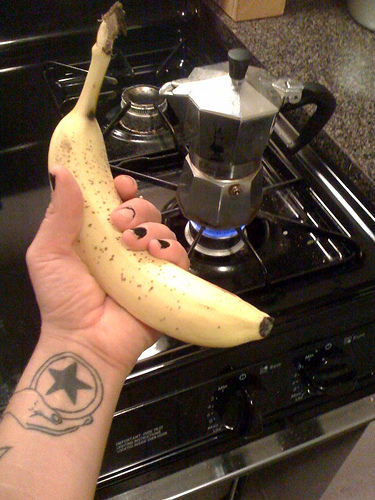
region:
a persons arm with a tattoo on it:
[3, 350, 105, 434]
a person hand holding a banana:
[29, 0, 273, 367]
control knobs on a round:
[206, 346, 361, 443]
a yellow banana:
[47, 1, 276, 346]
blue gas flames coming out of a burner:
[157, 183, 311, 267]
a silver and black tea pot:
[157, 36, 336, 229]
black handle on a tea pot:
[280, 74, 343, 158]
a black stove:
[0, 19, 373, 397]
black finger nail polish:
[129, 224, 157, 243]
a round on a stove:
[44, 37, 232, 155]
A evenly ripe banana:
[52, 30, 230, 360]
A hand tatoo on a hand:
[10, 403, 93, 434]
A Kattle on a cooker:
[161, 60, 334, 228]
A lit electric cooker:
[127, 34, 369, 454]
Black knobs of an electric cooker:
[212, 341, 358, 425]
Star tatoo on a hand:
[35, 350, 107, 411]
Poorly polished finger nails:
[106, 167, 174, 253]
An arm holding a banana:
[26, 132, 204, 438]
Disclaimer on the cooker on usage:
[113, 416, 190, 459]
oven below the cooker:
[204, 415, 373, 476]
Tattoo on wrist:
[1, 346, 106, 437]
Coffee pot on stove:
[154, 45, 334, 279]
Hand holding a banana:
[45, 0, 271, 345]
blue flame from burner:
[183, 216, 243, 239]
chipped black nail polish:
[114, 200, 164, 252]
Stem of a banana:
[78, 0, 123, 115]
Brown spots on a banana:
[80, 150, 95, 210]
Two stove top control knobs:
[205, 345, 347, 429]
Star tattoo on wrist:
[38, 360, 85, 396]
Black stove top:
[0, 0, 373, 336]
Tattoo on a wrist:
[27, 342, 107, 437]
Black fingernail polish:
[128, 221, 147, 241]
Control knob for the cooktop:
[208, 387, 256, 438]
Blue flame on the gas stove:
[189, 210, 249, 244]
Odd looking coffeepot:
[157, 46, 341, 238]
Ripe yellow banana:
[23, 21, 274, 350]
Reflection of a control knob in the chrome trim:
[273, 419, 330, 452]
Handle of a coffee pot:
[281, 62, 337, 157]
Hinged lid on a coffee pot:
[169, 40, 297, 132]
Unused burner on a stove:
[114, 73, 173, 131]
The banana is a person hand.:
[64, 222, 223, 360]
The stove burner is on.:
[156, 193, 244, 262]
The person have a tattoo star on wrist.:
[11, 347, 102, 433]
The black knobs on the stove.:
[205, 381, 271, 436]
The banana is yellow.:
[69, 112, 176, 337]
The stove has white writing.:
[105, 429, 176, 465]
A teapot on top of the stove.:
[157, 94, 290, 254]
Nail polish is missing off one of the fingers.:
[113, 191, 134, 223]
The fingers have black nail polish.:
[120, 219, 179, 261]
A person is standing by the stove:
[28, 165, 201, 373]